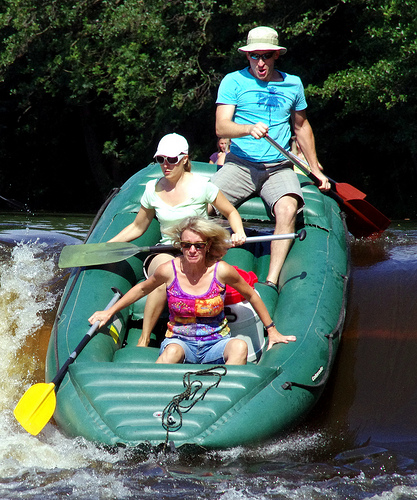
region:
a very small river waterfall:
[1, 245, 415, 453]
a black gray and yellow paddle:
[13, 284, 126, 437]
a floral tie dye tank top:
[162, 258, 228, 344]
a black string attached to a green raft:
[158, 365, 230, 458]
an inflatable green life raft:
[43, 158, 352, 455]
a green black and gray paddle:
[57, 230, 305, 269]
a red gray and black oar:
[260, 128, 388, 241]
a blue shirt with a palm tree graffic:
[213, 62, 308, 163]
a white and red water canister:
[222, 264, 267, 363]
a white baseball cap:
[149, 131, 191, 158]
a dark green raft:
[39, 148, 346, 452]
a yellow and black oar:
[13, 290, 117, 440]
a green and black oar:
[56, 228, 306, 268]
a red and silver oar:
[257, 129, 389, 233]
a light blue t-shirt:
[218, 68, 309, 162]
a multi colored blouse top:
[167, 256, 228, 339]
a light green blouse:
[138, 179, 217, 246]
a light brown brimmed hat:
[236, 24, 287, 54]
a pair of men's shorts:
[205, 152, 303, 213]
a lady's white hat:
[152, 133, 187, 156]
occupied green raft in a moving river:
[43, 156, 359, 454]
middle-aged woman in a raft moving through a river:
[84, 214, 299, 365]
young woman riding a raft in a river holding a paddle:
[107, 130, 255, 350]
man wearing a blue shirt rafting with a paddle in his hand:
[189, 24, 333, 295]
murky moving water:
[2, 440, 414, 498]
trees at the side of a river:
[0, 2, 415, 156]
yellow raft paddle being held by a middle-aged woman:
[10, 282, 128, 437]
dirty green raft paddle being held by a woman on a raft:
[56, 226, 312, 271]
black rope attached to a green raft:
[155, 364, 236, 456]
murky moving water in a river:
[1, 211, 96, 498]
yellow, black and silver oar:
[11, 284, 125, 436]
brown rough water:
[1, 214, 416, 498]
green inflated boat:
[44, 156, 351, 458]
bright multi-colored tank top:
[164, 256, 231, 339]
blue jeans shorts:
[158, 334, 236, 364]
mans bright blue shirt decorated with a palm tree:
[213, 67, 308, 162]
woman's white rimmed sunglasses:
[152, 154, 187, 164]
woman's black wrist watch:
[261, 319, 275, 330]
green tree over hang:
[0, 1, 415, 196]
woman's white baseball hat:
[152, 131, 188, 159]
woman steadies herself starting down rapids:
[83, 209, 297, 360]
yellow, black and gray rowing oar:
[10, 282, 124, 440]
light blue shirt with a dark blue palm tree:
[215, 63, 309, 166]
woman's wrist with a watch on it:
[258, 317, 296, 352]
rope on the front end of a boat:
[157, 357, 228, 454]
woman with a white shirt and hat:
[100, 128, 248, 256]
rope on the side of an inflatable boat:
[281, 186, 351, 394]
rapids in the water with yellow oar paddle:
[0, 233, 69, 495]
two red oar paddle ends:
[322, 165, 395, 243]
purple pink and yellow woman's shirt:
[153, 259, 233, 345]